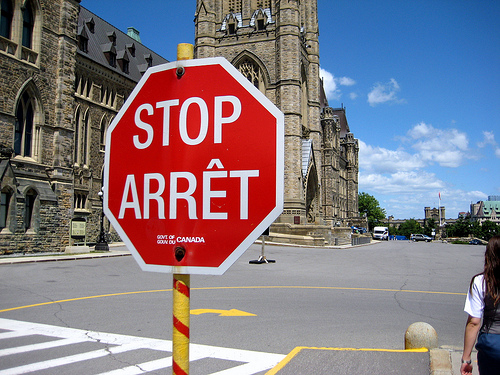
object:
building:
[200, 0, 356, 248]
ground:
[427, 162, 437, 181]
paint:
[0, 315, 282, 373]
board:
[105, 57, 286, 276]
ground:
[445, 148, 472, 188]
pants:
[476, 333, 498, 373]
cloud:
[362, 117, 473, 193]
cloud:
[315, 54, 399, 98]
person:
[455, 234, 499, 375]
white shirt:
[460, 269, 500, 335]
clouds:
[484, 138, 494, 171]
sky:
[410, 73, 491, 126]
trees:
[358, 192, 389, 224]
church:
[1, 0, 359, 262]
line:
[0, 282, 470, 316]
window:
[12, 83, 48, 162]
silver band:
[463, 353, 476, 361]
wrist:
[461, 358, 474, 366]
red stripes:
[170, 271, 194, 368]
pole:
[438, 200, 441, 232]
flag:
[438, 191, 442, 201]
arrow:
[187, 308, 257, 317]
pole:
[170, 272, 193, 374]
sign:
[100, 56, 284, 277]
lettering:
[118, 96, 261, 221]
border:
[138, 56, 234, 71]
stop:
[130, 90, 245, 149]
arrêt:
[118, 158, 261, 224]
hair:
[487, 241, 499, 275]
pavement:
[0, 235, 499, 375]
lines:
[0, 314, 283, 374]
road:
[0, 238, 500, 373]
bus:
[372, 226, 388, 240]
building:
[0, 1, 180, 258]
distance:
[30, 254, 494, 375]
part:
[337, 55, 485, 261]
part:
[115, 146, 236, 344]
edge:
[245, 315, 457, 375]